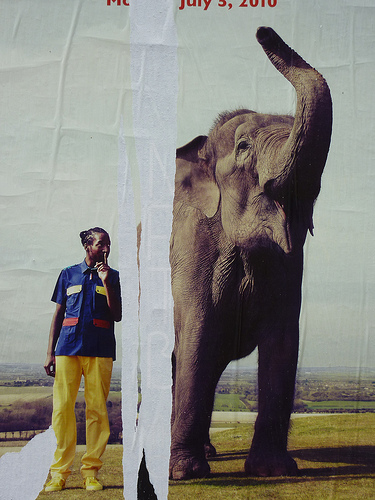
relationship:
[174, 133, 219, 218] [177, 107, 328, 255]
ear on side of head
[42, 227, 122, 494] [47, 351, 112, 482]
guy wearing yellow pants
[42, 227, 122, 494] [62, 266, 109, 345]
guy has on a blue shirt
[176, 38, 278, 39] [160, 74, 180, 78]
writing was cut off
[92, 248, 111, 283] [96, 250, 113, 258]
fingers near mouth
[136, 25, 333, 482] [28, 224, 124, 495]
elephant near guy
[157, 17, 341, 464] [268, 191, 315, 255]
elephant opening its mouth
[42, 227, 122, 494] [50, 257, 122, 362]
guy wearing blue shirt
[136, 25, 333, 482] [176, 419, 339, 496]
elephant on grass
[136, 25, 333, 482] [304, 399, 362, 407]
elephant on grass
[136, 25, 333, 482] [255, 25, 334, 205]
elephant has trunk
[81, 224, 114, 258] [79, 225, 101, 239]
hair in cornrows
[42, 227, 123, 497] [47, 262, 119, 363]
guy wearing blue shirt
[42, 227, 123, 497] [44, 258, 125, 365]
guy wears shirt